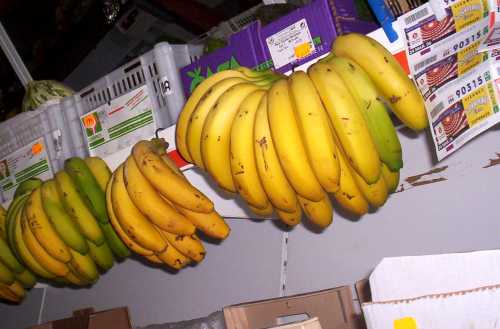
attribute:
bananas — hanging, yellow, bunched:
[0, 32, 428, 307]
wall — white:
[1, 125, 497, 326]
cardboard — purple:
[178, 1, 378, 100]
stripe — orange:
[167, 150, 191, 170]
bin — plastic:
[75, 39, 204, 159]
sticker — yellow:
[390, 316, 419, 328]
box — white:
[360, 248, 498, 329]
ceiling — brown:
[149, 0, 236, 30]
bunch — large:
[3, 31, 429, 304]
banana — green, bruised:
[64, 155, 108, 226]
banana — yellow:
[266, 80, 324, 204]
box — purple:
[179, 1, 378, 99]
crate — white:
[0, 93, 77, 202]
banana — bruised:
[133, 137, 214, 215]